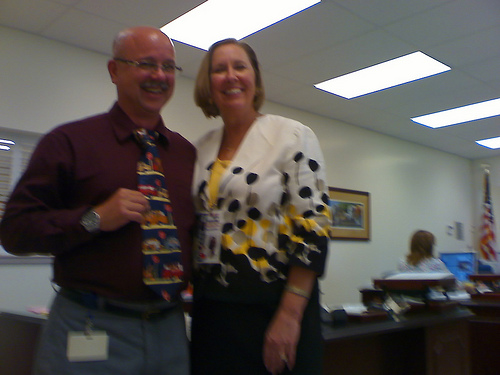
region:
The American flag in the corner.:
[477, 160, 499, 272]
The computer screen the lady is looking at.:
[440, 249, 475, 281]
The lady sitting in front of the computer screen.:
[392, 231, 439, 271]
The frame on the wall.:
[325, 180, 372, 246]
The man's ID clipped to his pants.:
[64, 310, 114, 361]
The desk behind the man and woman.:
[6, 293, 473, 373]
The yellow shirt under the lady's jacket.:
[212, 152, 229, 207]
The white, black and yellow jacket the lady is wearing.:
[192, 125, 319, 279]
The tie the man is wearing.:
[130, 129, 187, 308]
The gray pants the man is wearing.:
[35, 281, 187, 373]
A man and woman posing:
[1, 21, 338, 373]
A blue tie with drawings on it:
[129, 119, 187, 310]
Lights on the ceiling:
[158, 0, 498, 152]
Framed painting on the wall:
[322, 182, 374, 242]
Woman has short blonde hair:
[190, 38, 270, 123]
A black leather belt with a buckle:
[51, 284, 187, 328]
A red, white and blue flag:
[473, 161, 498, 265]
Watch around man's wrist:
[75, 201, 107, 242]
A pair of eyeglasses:
[110, 48, 187, 82]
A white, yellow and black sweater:
[189, 111, 333, 294]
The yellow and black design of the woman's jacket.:
[200, 154, 328, 287]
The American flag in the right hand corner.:
[477, 156, 498, 265]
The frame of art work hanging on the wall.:
[323, 184, 376, 241]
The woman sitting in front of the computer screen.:
[395, 222, 447, 279]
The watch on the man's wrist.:
[78, 201, 108, 231]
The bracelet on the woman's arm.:
[282, 283, 319, 307]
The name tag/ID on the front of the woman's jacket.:
[202, 200, 226, 267]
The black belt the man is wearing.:
[60, 293, 188, 325]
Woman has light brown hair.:
[195, 45, 288, 125]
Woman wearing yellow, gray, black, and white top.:
[178, 131, 358, 363]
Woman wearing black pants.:
[206, 315, 242, 347]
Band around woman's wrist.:
[282, 272, 318, 327]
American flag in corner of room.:
[470, 171, 499, 248]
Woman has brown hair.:
[401, 215, 433, 277]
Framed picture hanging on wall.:
[330, 174, 364, 271]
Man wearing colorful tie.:
[132, 135, 179, 269]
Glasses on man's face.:
[116, 49, 187, 94]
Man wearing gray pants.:
[51, 325, 160, 373]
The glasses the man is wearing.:
[114, 53, 181, 77]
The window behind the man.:
[5, 130, 60, 250]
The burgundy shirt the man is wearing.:
[2, 104, 192, 314]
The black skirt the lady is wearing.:
[195, 275, 311, 373]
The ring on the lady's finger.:
[275, 348, 289, 365]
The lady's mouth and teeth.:
[219, 85, 244, 97]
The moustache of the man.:
[137, 80, 171, 92]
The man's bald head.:
[117, 25, 176, 42]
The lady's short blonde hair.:
[185, 34, 268, 111]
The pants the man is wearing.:
[47, 300, 195, 373]